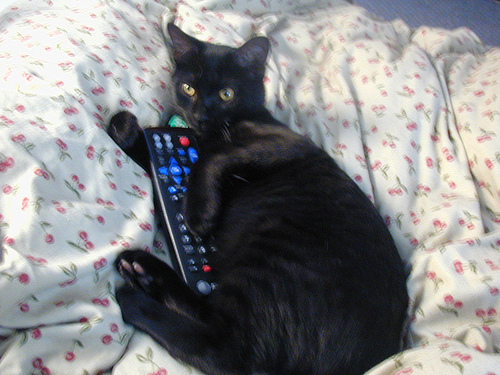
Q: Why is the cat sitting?
A: It is posing.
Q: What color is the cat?
A: Black.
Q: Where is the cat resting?
A: On the bed.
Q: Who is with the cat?
A: No one.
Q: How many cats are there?
A: 1.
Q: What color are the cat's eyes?
A: Yellow.